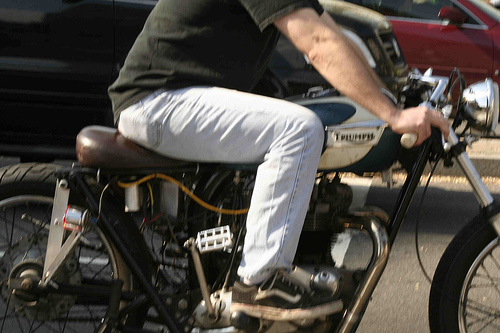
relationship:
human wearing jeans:
[121, 1, 407, 301] [116, 83, 326, 285]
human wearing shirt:
[121, 1, 407, 301] [108, 0, 325, 118]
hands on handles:
[397, 97, 445, 140] [400, 63, 458, 152]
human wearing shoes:
[106, 0, 450, 323] [229, 272, 349, 319]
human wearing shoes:
[106, 0, 450, 323] [229, 265, 348, 321]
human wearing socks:
[106, 0, 450, 323] [234, 267, 283, 286]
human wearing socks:
[106, 0, 450, 323] [232, 265, 281, 291]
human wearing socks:
[106, 0, 450, 323] [237, 267, 275, 288]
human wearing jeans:
[106, 0, 450, 323] [116, 83, 326, 285]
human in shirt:
[106, 0, 450, 323] [108, 0, 325, 118]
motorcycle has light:
[0, 62, 497, 332] [460, 72, 500, 133]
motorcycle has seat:
[0, 62, 497, 332] [74, 115, 123, 165]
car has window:
[341, 2, 499, 107] [382, 1, 466, 32]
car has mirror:
[341, 0, 500, 120] [438, 6, 469, 24]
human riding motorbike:
[106, 0, 450, 323] [4, 63, 499, 332]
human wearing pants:
[106, 0, 450, 323] [109, 83, 337, 267]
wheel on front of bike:
[395, 59, 451, 110] [0, 66, 497, 329]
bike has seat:
[0, 66, 497, 329] [74, 115, 123, 165]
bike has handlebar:
[0, 66, 497, 329] [402, 60, 456, 115]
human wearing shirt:
[106, 0, 450, 323] [113, 2, 285, 98]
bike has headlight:
[0, 66, 497, 329] [462, 72, 499, 134]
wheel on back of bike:
[395, 59, 451, 110] [0, 66, 497, 329]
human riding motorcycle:
[106, 0, 450, 323] [0, 62, 497, 332]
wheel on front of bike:
[427, 198, 497, 331] [0, 66, 497, 329]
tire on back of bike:
[1, 161, 151, 333] [0, 0, 495, 329]